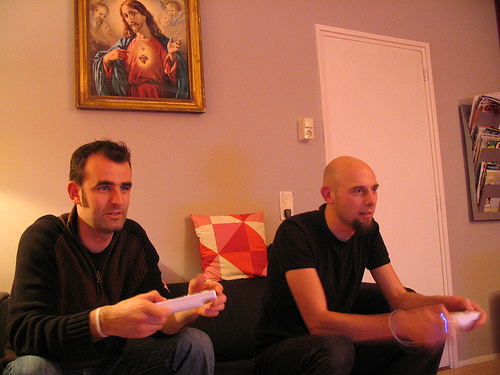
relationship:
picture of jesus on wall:
[75, 0, 207, 114] [2, 0, 498, 367]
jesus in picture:
[92, 3, 194, 101] [68, 0, 245, 140]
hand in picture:
[161, 33, 187, 68] [68, 0, 245, 140]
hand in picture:
[101, 47, 127, 60] [75, 0, 207, 114]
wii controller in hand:
[158, 288, 208, 320] [90, 291, 170, 336]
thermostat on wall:
[295, 114, 315, 147] [4, 7, 498, 305]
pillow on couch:
[185, 207, 268, 283] [163, 273, 445, 373]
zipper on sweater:
[87, 269, 113, 288] [24, 208, 174, 341]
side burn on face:
[67, 175, 97, 221] [77, 150, 133, 230]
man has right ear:
[248, 156, 487, 373] [320, 185, 332, 203]